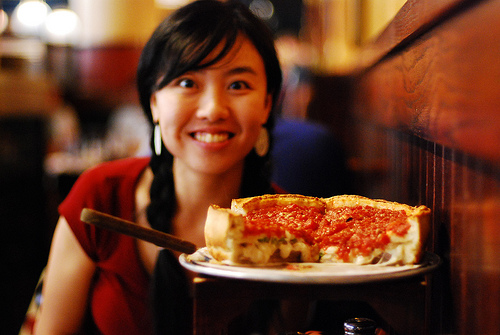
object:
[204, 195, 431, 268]
pizza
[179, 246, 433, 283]
plate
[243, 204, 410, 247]
sauce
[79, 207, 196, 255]
handle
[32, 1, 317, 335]
woman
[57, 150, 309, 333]
shirt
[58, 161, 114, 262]
sleeve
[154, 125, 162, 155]
earring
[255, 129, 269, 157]
earring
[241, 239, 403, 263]
cheese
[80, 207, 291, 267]
utensil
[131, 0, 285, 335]
hair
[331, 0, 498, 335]
wall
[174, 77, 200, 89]
eye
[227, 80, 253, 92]
eye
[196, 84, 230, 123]
nose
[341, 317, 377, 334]
shaker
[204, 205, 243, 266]
crust